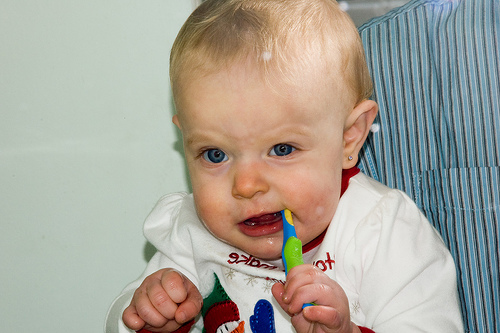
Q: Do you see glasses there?
A: No, there are no glasses.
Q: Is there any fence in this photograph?
A: No, there are no fences.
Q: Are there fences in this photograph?
A: No, there are no fences.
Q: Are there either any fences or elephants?
A: No, there are no fences or elephants.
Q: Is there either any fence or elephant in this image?
A: No, there are no fences or elephants.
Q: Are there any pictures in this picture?
A: No, there are no pictures.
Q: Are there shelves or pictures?
A: No, there are no pictures or shelves.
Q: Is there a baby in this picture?
A: Yes, there is a baby.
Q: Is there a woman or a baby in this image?
A: Yes, there is a baby.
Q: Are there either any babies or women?
A: Yes, there is a baby.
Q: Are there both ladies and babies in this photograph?
A: No, there is a baby but no ladies.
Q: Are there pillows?
A: No, there are no pillows.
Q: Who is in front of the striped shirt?
A: The baby is in front of the shirt.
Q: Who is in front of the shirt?
A: The baby is in front of the shirt.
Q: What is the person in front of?
A: The baby is in front of the shirt.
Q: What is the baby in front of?
A: The baby is in front of the shirt.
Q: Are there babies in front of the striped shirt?
A: Yes, there is a baby in front of the shirt.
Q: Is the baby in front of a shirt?
A: Yes, the baby is in front of a shirt.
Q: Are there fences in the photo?
A: No, there are no fences.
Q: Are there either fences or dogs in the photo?
A: No, there are no fences or dogs.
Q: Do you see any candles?
A: No, there are no candles.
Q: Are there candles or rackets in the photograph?
A: No, there are no candles or rackets.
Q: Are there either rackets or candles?
A: No, there are no candles or rackets.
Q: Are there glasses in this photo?
A: No, there are no glasses.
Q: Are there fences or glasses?
A: No, there are no glasses or fences.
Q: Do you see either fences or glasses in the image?
A: No, there are no glasses or fences.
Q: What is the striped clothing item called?
A: The clothing item is a shirt.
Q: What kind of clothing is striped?
A: The clothing is a shirt.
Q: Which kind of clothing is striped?
A: The clothing is a shirt.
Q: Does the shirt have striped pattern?
A: Yes, the shirt is striped.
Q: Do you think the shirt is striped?
A: Yes, the shirt is striped.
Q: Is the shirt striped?
A: Yes, the shirt is striped.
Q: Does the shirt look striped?
A: Yes, the shirt is striped.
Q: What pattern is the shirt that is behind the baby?
A: The shirt is striped.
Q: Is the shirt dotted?
A: No, the shirt is striped.